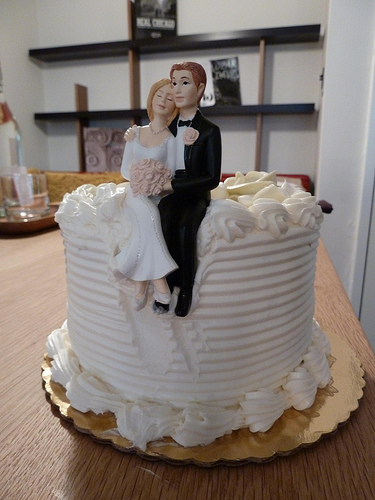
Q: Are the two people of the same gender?
A: No, they are both male and female.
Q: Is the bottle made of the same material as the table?
A: No, the bottle is made of glass and the table is made of wood.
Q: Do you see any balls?
A: No, there are no balls.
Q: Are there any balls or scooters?
A: No, there are no balls or scooters.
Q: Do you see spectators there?
A: No, there are no spectators.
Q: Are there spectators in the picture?
A: No, there are no spectators.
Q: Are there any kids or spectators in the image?
A: No, there are no spectators or kids.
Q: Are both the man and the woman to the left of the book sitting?
A: Yes, both the man and the woman are sitting.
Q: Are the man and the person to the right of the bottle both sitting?
A: Yes, both the man and the woman are sitting.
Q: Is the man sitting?
A: Yes, the man is sitting.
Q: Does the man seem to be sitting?
A: Yes, the man is sitting.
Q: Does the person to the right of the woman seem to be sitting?
A: Yes, the man is sitting.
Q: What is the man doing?
A: The man is sitting.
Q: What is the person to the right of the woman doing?
A: The man is sitting.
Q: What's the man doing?
A: The man is sitting.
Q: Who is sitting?
A: The man is sitting.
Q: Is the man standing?
A: No, the man is sitting.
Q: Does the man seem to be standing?
A: No, the man is sitting.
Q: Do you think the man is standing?
A: No, the man is sitting.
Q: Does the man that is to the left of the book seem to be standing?
A: No, the man is sitting.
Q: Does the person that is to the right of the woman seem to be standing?
A: No, the man is sitting.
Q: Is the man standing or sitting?
A: The man is sitting.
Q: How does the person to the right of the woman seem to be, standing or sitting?
A: The man is sitting.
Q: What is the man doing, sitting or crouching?
A: The man is sitting.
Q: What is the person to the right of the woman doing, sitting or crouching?
A: The man is sitting.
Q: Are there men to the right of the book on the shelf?
A: No, the man is to the left of the book.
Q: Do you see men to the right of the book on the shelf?
A: No, the man is to the left of the book.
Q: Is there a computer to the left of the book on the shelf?
A: No, there is a man to the left of the book.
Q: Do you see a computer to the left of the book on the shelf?
A: No, there is a man to the left of the book.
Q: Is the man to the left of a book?
A: Yes, the man is to the left of a book.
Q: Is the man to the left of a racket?
A: No, the man is to the left of a book.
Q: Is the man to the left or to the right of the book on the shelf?
A: The man is to the left of the book.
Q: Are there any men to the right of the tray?
A: Yes, there is a man to the right of the tray.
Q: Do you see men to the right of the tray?
A: Yes, there is a man to the right of the tray.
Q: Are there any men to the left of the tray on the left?
A: No, the man is to the right of the tray.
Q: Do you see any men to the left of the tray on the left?
A: No, the man is to the right of the tray.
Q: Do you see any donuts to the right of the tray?
A: No, there is a man to the right of the tray.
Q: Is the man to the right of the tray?
A: Yes, the man is to the right of the tray.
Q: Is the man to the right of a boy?
A: No, the man is to the right of the tray.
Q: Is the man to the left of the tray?
A: No, the man is to the right of the tray.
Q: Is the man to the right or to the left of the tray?
A: The man is to the right of the tray.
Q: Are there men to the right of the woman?
A: Yes, there is a man to the right of the woman.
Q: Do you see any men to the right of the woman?
A: Yes, there is a man to the right of the woman.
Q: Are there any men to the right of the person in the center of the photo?
A: Yes, there is a man to the right of the woman.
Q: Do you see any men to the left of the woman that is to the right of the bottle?
A: No, the man is to the right of the woman.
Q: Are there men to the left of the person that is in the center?
A: No, the man is to the right of the woman.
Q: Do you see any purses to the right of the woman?
A: No, there is a man to the right of the woman.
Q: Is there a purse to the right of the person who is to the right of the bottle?
A: No, there is a man to the right of the woman.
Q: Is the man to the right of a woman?
A: Yes, the man is to the right of a woman.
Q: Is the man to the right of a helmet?
A: No, the man is to the right of a woman.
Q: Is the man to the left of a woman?
A: No, the man is to the right of a woman.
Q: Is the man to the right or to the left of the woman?
A: The man is to the right of the woman.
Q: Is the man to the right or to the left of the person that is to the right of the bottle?
A: The man is to the right of the woman.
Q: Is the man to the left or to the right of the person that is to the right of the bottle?
A: The man is to the right of the woman.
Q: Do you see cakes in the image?
A: Yes, there is a cake.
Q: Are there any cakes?
A: Yes, there is a cake.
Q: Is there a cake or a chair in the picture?
A: Yes, there is a cake.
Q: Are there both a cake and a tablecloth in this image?
A: No, there is a cake but no tablecloths.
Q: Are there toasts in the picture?
A: No, there are no toasts.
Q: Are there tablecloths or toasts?
A: No, there are no toasts or tablecloths.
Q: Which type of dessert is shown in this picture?
A: The dessert is a cake.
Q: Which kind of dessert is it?
A: The dessert is a cake.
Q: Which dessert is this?
A: This is a cake.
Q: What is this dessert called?
A: This is a cake.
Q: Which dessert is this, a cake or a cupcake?
A: This is a cake.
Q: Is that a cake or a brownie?
A: That is a cake.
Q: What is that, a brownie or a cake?
A: That is a cake.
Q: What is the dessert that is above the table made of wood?
A: The dessert is a cake.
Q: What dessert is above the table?
A: The dessert is a cake.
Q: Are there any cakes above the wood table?
A: Yes, there is a cake above the table.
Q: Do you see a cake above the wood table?
A: Yes, there is a cake above the table.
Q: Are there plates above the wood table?
A: No, there is a cake above the table.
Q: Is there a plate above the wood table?
A: No, there is a cake above the table.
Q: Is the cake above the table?
A: Yes, the cake is above the table.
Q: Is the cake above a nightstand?
A: No, the cake is above the table.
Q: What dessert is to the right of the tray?
A: The dessert is a cake.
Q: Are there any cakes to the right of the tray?
A: Yes, there is a cake to the right of the tray.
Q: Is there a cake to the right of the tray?
A: Yes, there is a cake to the right of the tray.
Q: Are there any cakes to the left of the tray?
A: No, the cake is to the right of the tray.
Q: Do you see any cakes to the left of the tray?
A: No, the cake is to the right of the tray.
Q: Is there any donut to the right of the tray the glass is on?
A: No, there is a cake to the right of the tray.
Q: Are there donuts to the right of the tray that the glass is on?
A: No, there is a cake to the right of the tray.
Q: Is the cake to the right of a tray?
A: Yes, the cake is to the right of a tray.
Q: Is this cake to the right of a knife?
A: No, the cake is to the right of a tray.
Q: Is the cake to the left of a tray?
A: No, the cake is to the right of a tray.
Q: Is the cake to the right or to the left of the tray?
A: The cake is to the right of the tray.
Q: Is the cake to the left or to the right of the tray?
A: The cake is to the right of the tray.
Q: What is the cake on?
A: The cake is on the frosting.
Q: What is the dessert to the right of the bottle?
A: The dessert is a cake.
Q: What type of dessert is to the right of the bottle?
A: The dessert is a cake.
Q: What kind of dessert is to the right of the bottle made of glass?
A: The dessert is a cake.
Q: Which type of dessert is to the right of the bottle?
A: The dessert is a cake.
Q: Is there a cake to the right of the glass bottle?
A: Yes, there is a cake to the right of the bottle.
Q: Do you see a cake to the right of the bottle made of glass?
A: Yes, there is a cake to the right of the bottle.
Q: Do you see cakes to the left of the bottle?
A: No, the cake is to the right of the bottle.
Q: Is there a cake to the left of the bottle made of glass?
A: No, the cake is to the right of the bottle.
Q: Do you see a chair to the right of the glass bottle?
A: No, there is a cake to the right of the bottle.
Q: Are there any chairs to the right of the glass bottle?
A: No, there is a cake to the right of the bottle.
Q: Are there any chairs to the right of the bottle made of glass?
A: No, there is a cake to the right of the bottle.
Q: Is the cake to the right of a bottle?
A: Yes, the cake is to the right of a bottle.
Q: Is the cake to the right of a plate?
A: No, the cake is to the right of a bottle.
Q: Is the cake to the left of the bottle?
A: No, the cake is to the right of the bottle.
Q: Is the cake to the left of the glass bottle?
A: No, the cake is to the right of the bottle.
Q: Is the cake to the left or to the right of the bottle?
A: The cake is to the right of the bottle.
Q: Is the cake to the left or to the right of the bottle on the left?
A: The cake is to the right of the bottle.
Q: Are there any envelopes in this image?
A: No, there are no envelopes.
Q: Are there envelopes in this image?
A: No, there are no envelopes.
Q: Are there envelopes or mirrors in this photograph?
A: No, there are no envelopes or mirrors.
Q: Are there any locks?
A: No, there are no locks.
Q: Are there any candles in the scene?
A: No, there are no candles.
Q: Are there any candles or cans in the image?
A: No, there are no candles or cans.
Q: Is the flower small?
A: Yes, the flower is small.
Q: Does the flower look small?
A: Yes, the flower is small.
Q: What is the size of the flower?
A: The flower is small.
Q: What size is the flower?
A: The flower is small.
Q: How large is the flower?
A: The flower is small.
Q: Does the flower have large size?
A: No, the flower is small.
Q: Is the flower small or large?
A: The flower is small.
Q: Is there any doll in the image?
A: Yes, there is a doll.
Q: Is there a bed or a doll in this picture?
A: Yes, there is a doll.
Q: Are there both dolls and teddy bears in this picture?
A: No, there is a doll but no teddy bears.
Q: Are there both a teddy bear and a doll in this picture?
A: No, there is a doll but no teddy bears.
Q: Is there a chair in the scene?
A: No, there are no chairs.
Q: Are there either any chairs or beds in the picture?
A: No, there are no chairs or beds.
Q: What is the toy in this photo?
A: The toy is a doll.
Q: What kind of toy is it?
A: The toy is a doll.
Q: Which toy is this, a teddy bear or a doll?
A: This is a doll.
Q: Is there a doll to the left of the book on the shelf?
A: Yes, there is a doll to the left of the book.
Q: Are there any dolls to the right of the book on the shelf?
A: No, the doll is to the left of the book.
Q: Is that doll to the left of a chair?
A: No, the doll is to the left of the book.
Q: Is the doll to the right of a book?
A: No, the doll is to the left of a book.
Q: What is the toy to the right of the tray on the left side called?
A: The toy is a doll.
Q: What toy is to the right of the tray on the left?
A: The toy is a doll.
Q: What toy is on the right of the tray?
A: The toy is a doll.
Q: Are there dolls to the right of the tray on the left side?
A: Yes, there is a doll to the right of the tray.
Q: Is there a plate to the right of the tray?
A: No, there is a doll to the right of the tray.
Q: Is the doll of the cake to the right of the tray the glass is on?
A: Yes, the doll is to the right of the tray.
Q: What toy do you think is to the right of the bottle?
A: The toy is a doll.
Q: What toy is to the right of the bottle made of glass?
A: The toy is a doll.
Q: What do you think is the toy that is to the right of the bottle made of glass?
A: The toy is a doll.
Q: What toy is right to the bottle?
A: The toy is a doll.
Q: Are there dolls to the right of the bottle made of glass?
A: Yes, there is a doll to the right of the bottle.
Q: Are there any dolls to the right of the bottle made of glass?
A: Yes, there is a doll to the right of the bottle.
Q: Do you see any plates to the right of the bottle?
A: No, there is a doll to the right of the bottle.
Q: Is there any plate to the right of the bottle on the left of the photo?
A: No, there is a doll to the right of the bottle.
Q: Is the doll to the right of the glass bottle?
A: Yes, the doll is to the right of the bottle.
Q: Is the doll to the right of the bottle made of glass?
A: Yes, the doll is to the right of the bottle.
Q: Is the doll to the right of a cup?
A: No, the doll is to the right of the bottle.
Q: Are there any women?
A: Yes, there is a woman.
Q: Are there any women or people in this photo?
A: Yes, there is a woman.